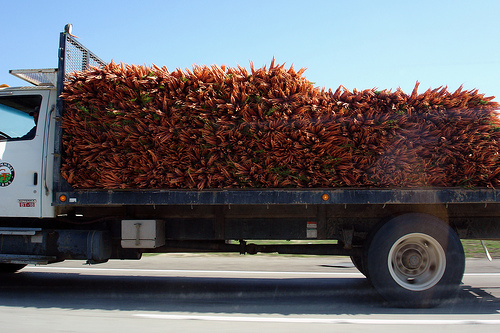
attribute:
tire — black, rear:
[347, 217, 497, 309]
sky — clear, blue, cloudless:
[378, 11, 445, 53]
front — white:
[0, 76, 61, 277]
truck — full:
[2, 16, 499, 319]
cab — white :
[1, 133, 48, 208]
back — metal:
[55, 22, 119, 189]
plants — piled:
[189, 114, 377, 165]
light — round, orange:
[58, 188, 75, 211]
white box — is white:
[121, 222, 157, 247]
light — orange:
[55, 192, 70, 202]